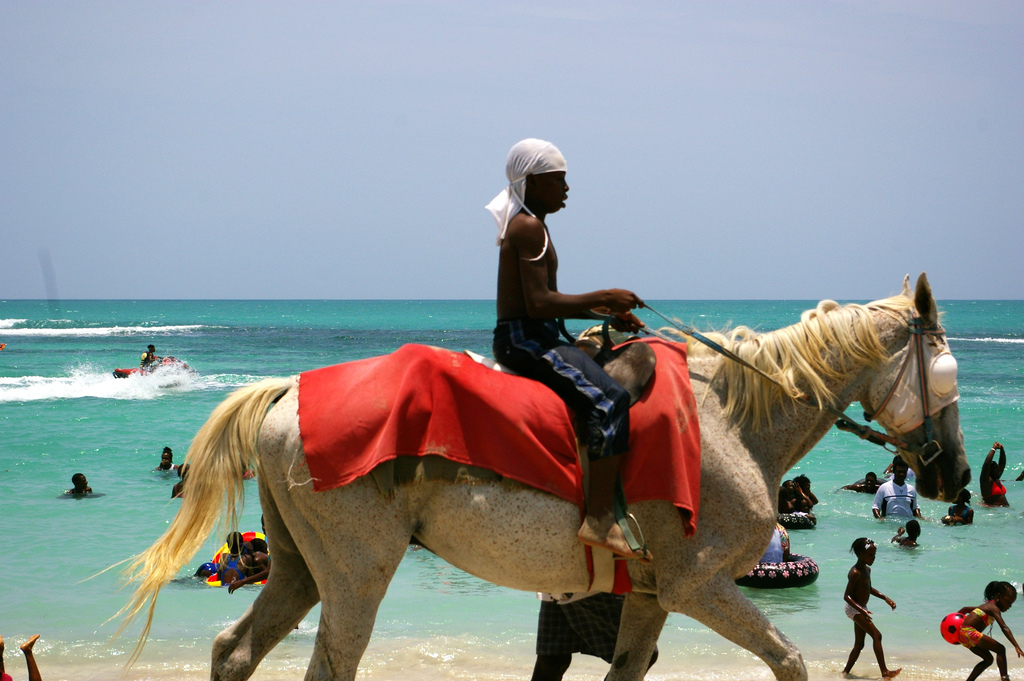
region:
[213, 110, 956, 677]
person riding tan horse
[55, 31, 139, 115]
white clouds in blue sky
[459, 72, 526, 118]
white clouds in blue sky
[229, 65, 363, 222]
blue and white sky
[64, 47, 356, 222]
white clouds in sky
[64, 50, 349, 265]
faint clouds in sky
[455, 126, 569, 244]
man has white cloth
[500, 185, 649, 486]
man has blue pants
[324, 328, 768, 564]
red blanket on horse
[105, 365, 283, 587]
golden tail on horse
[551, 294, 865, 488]
golden mane on horse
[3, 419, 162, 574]
water is bright blue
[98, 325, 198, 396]
red jet-ski on water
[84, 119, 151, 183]
white clouds in blue sky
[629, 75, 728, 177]
white clouds in blue sky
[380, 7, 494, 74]
white clouds in blue sky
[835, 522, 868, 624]
A person eating a orange.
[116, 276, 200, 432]
A person eating a orange.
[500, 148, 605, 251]
man has white cap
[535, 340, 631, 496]
man has blue pants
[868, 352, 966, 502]
horse has brown face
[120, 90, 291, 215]
blue and clear sky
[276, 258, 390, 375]
water is bright blue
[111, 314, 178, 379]
red speedboat on water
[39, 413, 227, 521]
people playing in water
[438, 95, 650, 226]
head of the man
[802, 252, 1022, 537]
head of the animal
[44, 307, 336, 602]
tail of the horse